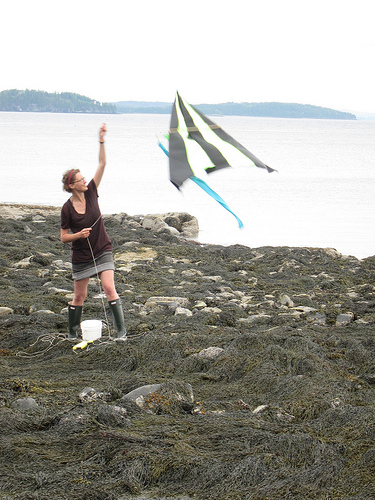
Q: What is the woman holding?
A: Kite.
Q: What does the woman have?
A: A kite.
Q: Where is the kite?
A: The air.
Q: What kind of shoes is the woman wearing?
A: Boots.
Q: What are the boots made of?
A: Rubber.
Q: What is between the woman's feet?
A: Bucket.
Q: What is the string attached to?
A: The kite.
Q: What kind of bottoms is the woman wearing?
A: A skirt.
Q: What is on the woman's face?
A: Glasses.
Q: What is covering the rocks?
A: Seaweed.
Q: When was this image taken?
A: During the afternoon.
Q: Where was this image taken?
A: On a rocky shore, covered in seaweed.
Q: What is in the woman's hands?
A: A rope attached to a kite.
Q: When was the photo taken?
A: Daytime.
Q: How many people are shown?
A: One.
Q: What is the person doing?
A: Flying a kite.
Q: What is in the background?
A: Hills.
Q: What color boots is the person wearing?
A: Black.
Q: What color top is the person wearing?
A: Brown.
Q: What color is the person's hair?
A: Red.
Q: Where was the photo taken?
A: At the beach.